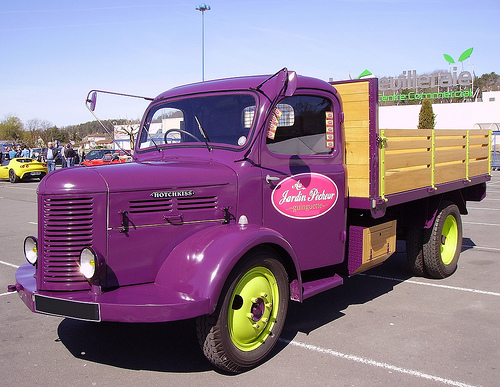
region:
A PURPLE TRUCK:
[5, 63, 498, 375]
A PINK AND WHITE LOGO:
[269, 171, 339, 219]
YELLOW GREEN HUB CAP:
[223, 261, 289, 353]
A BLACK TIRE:
[198, 244, 299, 377]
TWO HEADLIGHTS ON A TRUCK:
[21, 231, 116, 282]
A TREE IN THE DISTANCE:
[410, 92, 445, 132]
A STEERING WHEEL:
[162, 126, 204, 148]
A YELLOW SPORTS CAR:
[0, 149, 50, 189]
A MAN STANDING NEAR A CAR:
[36, 141, 60, 178]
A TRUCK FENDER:
[2, 263, 112, 336]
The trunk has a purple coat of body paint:
[5, 56, 496, 382]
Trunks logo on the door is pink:
[264, 163, 346, 230]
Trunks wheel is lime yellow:
[189, 247, 321, 364]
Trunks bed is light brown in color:
[324, 69, 498, 262]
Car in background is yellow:
[0, 141, 52, 186]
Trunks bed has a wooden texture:
[328, 74, 498, 244]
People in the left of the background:
[38, 128, 79, 180]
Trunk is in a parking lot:
[2, 159, 498, 384]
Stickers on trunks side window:
[318, 103, 339, 150]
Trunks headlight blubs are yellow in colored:
[24, 234, 120, 280]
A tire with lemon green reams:
[206, 246, 304, 363]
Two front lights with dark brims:
[6, 233, 106, 278]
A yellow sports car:
[0, 155, 45, 181]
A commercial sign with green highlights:
[367, 47, 482, 102]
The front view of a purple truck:
[52, 53, 334, 355]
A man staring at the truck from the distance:
[39, 133, 58, 170]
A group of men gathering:
[5, 141, 38, 158]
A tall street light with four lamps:
[189, 3, 221, 81]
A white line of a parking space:
[320, 348, 456, 381]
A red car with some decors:
[78, 147, 131, 163]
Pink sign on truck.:
[267, 170, 340, 219]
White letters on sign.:
[278, 188, 335, 205]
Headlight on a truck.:
[74, 243, 99, 285]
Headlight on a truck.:
[16, 234, 43, 267]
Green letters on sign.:
[373, 85, 482, 102]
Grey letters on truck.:
[146, 188, 197, 200]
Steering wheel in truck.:
[161, 126, 203, 147]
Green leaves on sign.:
[440, 45, 477, 65]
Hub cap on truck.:
[225, 259, 282, 356]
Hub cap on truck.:
[429, 210, 461, 267]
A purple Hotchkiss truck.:
[3, 4, 498, 384]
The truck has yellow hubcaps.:
[219, 205, 471, 360]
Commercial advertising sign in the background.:
[363, 45, 485, 110]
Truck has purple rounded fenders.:
[105, 212, 320, 312]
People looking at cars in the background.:
[1, 125, 136, 181]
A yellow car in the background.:
[1, 149, 52, 184]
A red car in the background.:
[80, 140, 129, 170]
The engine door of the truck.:
[91, 151, 255, 241]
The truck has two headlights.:
[11, 222, 111, 303]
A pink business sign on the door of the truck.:
[261, 160, 347, 229]